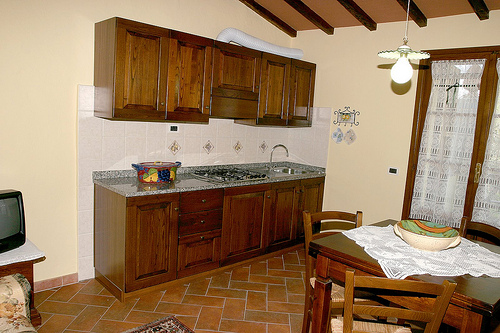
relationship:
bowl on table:
[385, 215, 469, 253] [296, 210, 500, 326]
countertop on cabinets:
[84, 154, 329, 199] [92, 156, 329, 302]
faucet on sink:
[270, 142, 290, 171] [258, 160, 307, 183]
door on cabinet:
[114, 18, 168, 127] [86, 14, 330, 309]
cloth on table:
[340, 217, 498, 309] [296, 210, 500, 326]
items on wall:
[333, 100, 362, 148] [267, 4, 499, 250]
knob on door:
[472, 160, 484, 195] [398, 41, 499, 243]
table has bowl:
[296, 210, 500, 326] [385, 215, 469, 253]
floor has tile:
[32, 242, 446, 332] [21, 228, 455, 331]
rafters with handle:
[266, 1, 304, 42] [130, 162, 139, 168]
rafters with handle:
[266, 1, 304, 42] [176, 158, 184, 168]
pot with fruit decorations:
[141, 146, 179, 191] [126, 167, 190, 185]